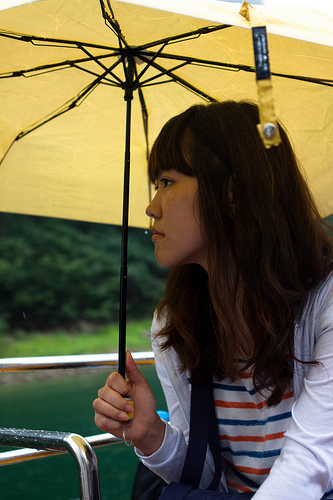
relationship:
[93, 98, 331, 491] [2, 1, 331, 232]
girl holding umbrella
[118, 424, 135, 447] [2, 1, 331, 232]
ring on umbrella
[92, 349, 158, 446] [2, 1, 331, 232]
hand holding umbrella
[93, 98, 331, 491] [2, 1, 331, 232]
woman holding umbrella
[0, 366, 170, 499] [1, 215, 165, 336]
lake near trees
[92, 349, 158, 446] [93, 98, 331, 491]
hand at woman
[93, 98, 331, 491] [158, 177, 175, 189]
woman has eye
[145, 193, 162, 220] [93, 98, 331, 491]
nose on woman